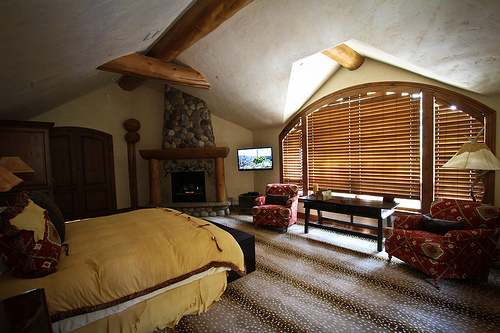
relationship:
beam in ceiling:
[320, 42, 363, 69] [1, 0, 498, 132]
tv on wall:
[235, 145, 271, 170] [218, 59, 443, 198]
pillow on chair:
[418, 210, 461, 236] [382, 194, 499, 284]